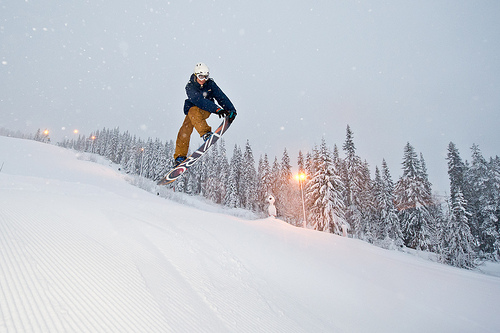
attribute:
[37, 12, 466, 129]
sky — white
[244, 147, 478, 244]
trees — tall, white, green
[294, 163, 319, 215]
pole — glowing, bright, tall, yellow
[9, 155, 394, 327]
snow — white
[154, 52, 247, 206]
man — snowboarding, white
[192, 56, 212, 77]
helmet — white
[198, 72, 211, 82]
goggles — white, on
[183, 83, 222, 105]
coat — blue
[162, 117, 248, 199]
board — black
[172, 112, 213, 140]
pants — brown